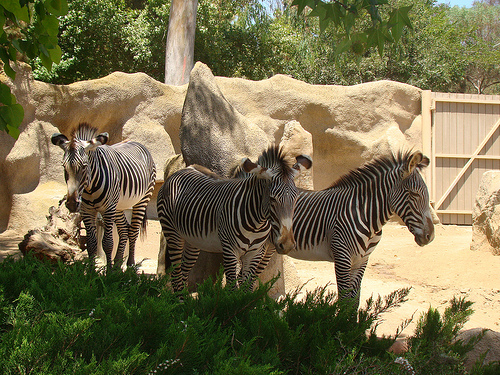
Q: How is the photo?
A: Clear.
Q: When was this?
A: Daytime.